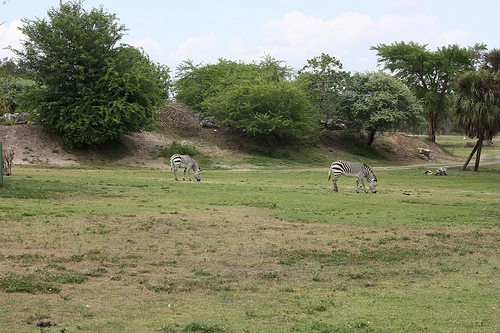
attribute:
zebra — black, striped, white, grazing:
[156, 142, 207, 197]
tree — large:
[395, 36, 472, 143]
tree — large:
[448, 53, 499, 176]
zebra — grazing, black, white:
[166, 152, 203, 182]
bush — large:
[2, 4, 179, 156]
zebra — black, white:
[168, 150, 201, 185]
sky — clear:
[2, 3, 495, 107]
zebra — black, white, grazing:
[323, 156, 381, 196]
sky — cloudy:
[0, 2, 499, 77]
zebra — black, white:
[317, 150, 391, 204]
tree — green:
[1, 0, 166, 148]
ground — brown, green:
[1, 118, 498, 329]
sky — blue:
[0, 0, 500, 96]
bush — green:
[200, 75, 324, 146]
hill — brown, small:
[2, 112, 444, 173]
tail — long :
[326, 163, 335, 183]